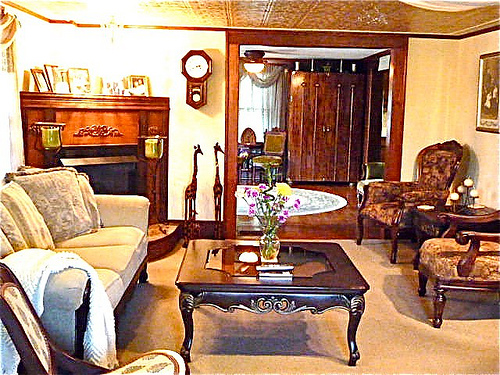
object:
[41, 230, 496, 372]
floor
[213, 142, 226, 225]
giraffe statue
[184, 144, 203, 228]
giraffe statue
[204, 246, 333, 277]
insert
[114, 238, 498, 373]
carpeting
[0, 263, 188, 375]
furniture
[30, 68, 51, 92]
frames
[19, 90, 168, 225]
mantle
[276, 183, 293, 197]
flower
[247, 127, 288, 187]
chair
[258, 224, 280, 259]
vase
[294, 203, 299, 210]
flowers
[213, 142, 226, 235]
statue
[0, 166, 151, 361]
couch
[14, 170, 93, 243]
pillows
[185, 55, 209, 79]
round face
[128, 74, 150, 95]
famile photos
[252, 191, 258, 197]
flowers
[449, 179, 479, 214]
candles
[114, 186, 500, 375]
ground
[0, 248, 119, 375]
blanket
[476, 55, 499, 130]
wall painting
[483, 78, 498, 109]
people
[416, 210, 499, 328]
armchair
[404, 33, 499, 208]
wall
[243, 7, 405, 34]
tiles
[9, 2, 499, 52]
ceiling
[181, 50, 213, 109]
clock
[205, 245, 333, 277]
glass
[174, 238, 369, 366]
coffee table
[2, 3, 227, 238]
wall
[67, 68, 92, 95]
family photos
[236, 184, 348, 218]
rug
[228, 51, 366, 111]
brass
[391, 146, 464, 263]
framed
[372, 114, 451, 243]
corner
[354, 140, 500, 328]
two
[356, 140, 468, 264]
arm chair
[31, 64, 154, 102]
lots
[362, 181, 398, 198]
brown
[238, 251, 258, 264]
candles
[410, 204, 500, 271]
table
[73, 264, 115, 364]
white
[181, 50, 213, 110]
wooden